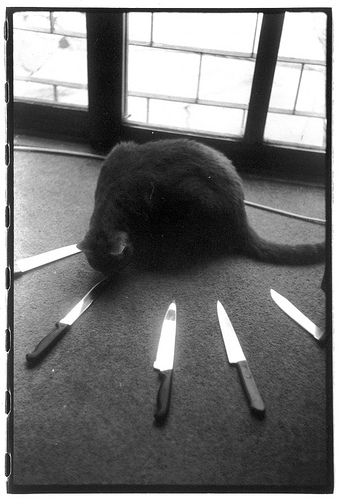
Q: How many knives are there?
A: 5.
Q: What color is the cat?
A: Black.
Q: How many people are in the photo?
A: 0.